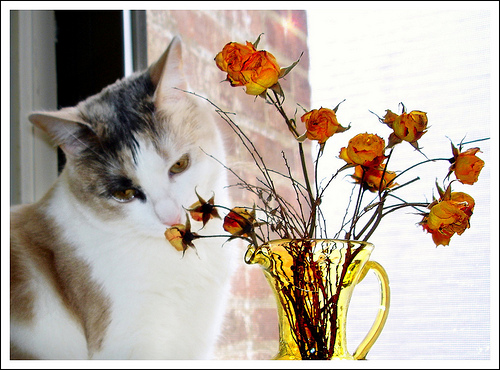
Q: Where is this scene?
A: Living room.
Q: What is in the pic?
A: Cat.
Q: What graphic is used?
A: Flowers.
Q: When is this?
A: Daytime.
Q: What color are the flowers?
A: Orange.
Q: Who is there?
A: Nobody.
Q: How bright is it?
A: Very bright.